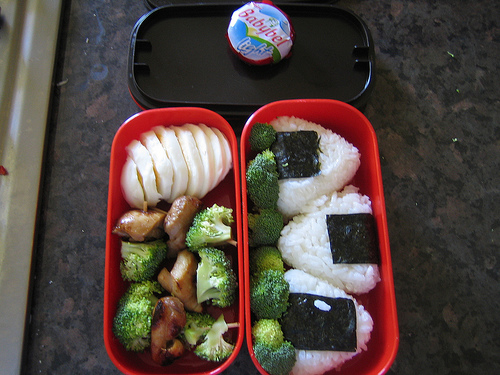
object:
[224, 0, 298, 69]
cheese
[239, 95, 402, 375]
container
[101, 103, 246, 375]
container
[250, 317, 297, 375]
broccoli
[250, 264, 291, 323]
broccoli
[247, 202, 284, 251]
broccoli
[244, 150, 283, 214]
broccoli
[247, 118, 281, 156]
broccoli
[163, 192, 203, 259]
chicken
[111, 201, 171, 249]
chicken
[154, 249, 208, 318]
chicken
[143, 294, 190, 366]
chicken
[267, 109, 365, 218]
rice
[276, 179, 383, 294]
rice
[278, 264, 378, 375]
rice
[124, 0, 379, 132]
lid